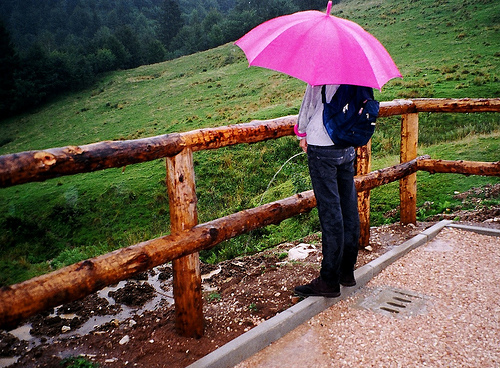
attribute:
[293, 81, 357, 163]
shirt — white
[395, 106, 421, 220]
wooden post — thick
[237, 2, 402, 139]
umbrella —  pink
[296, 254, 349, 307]
shoe — black 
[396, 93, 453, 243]
post — thick, wooden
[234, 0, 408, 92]
umbrella — pink, pink fabric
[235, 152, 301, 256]
stream — urine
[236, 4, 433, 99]
umbrella — pink 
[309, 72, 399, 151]
backpack — blue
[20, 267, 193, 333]
snow — frozen 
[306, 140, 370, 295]
jeans — person's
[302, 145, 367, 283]
jeans — blue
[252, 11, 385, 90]
umbrella — pink 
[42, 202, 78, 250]
weeds — green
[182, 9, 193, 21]
leaf — green 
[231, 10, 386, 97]
umbrella — pink , top  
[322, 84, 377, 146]
backpack — blue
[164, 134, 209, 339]
post — thick, wooden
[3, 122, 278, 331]
log fence —  log 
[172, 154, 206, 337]
wood — brown 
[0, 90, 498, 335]
fence — wooden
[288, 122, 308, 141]
handle — pink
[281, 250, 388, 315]
shoes — black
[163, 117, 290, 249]
fence — wooden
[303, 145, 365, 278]
denim jeans — dark blue denim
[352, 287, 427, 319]
drain — cement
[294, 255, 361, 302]
boots — black suede ankle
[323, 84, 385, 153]
back —  person's 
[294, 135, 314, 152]
tip — pink 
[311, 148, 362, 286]
jeans —  black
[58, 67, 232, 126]
field — grass 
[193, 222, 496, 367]
curb — poured cement